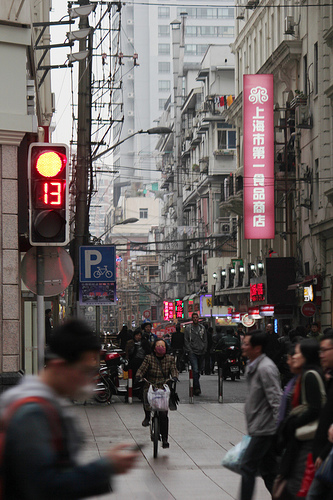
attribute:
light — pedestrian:
[25, 140, 71, 250]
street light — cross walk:
[26, 142, 67, 246]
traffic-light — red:
[28, 143, 69, 246]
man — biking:
[139, 340, 175, 456]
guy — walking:
[2, 322, 138, 499]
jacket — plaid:
[138, 355, 179, 384]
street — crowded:
[70, 306, 329, 498]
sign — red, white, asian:
[242, 73, 276, 239]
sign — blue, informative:
[78, 243, 118, 285]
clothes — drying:
[217, 95, 232, 106]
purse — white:
[297, 419, 323, 439]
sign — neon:
[246, 282, 265, 300]